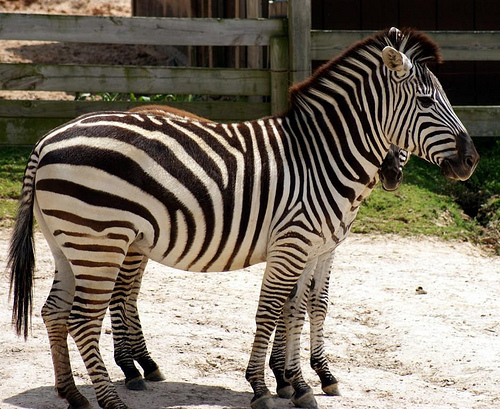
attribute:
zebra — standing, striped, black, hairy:
[5, 25, 482, 408]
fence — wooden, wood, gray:
[0, 1, 499, 142]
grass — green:
[1, 147, 496, 233]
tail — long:
[4, 156, 43, 341]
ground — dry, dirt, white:
[1, 236, 498, 409]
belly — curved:
[133, 240, 265, 278]